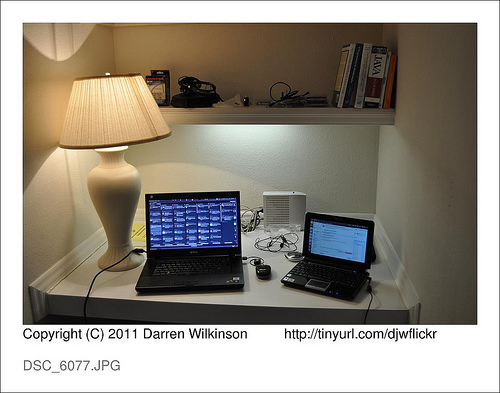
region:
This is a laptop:
[276, 205, 386, 313]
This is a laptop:
[126, 174, 263, 303]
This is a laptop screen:
[144, 194, 241, 246]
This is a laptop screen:
[309, 216, 377, 271]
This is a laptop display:
[144, 194, 239, 246]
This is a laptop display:
[304, 214, 389, 271]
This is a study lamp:
[64, 63, 170, 277]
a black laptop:
[135, 191, 244, 295]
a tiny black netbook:
[284, 212, 374, 305]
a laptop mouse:
[253, 259, 270, 279]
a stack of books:
[330, 42, 400, 113]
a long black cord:
[80, 243, 145, 325]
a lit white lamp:
[57, 68, 169, 268]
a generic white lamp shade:
[57, 70, 164, 152]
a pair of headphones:
[178, 75, 225, 98]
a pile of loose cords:
[255, 229, 302, 255]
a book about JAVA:
[365, 46, 386, 103]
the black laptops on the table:
[133, 191, 375, 311]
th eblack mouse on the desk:
[244, 251, 276, 284]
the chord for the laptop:
[72, 243, 145, 323]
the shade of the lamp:
[59, 62, 171, 149]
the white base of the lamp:
[87, 144, 144, 272]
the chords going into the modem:
[239, 205, 261, 232]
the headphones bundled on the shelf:
[170, 67, 220, 93]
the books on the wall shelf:
[332, 27, 401, 111]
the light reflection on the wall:
[25, 21, 97, 71]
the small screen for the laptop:
[306, 221, 366, 268]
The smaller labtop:
[290, 216, 371, 298]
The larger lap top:
[142, 201, 246, 296]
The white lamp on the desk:
[58, 63, 178, 275]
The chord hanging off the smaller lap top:
[351, 276, 378, 323]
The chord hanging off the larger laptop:
[62, 256, 149, 316]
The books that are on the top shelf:
[341, 39, 392, 114]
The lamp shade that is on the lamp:
[61, 75, 166, 150]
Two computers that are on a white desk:
[144, 188, 384, 312]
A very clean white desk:
[60, 176, 418, 323]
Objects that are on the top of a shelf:
[121, 32, 381, 107]